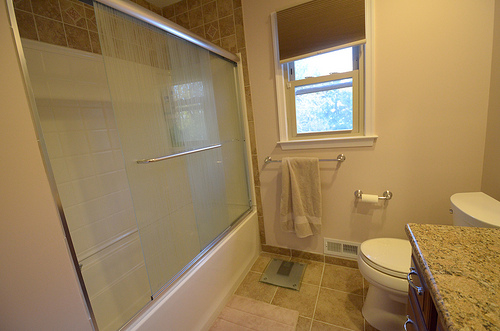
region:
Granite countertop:
[401, 204, 499, 321]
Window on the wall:
[248, 5, 398, 177]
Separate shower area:
[14, 4, 325, 314]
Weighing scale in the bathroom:
[261, 249, 321, 319]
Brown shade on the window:
[271, 1, 417, 101]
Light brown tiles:
[246, 283, 356, 328]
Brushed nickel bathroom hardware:
[99, 0, 433, 238]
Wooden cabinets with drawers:
[398, 242, 429, 329]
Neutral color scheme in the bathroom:
[4, 1, 493, 313]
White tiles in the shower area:
[51, 87, 228, 268]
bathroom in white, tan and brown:
[10, 13, 490, 318]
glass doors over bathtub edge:
[10, 6, 271, 321]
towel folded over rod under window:
[260, 146, 336, 242]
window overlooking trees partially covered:
[260, 1, 380, 151]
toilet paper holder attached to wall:
[342, 180, 392, 215]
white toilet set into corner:
[350, 147, 495, 317]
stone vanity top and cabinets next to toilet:
[400, 205, 492, 325]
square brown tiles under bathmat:
[230, 287, 362, 322]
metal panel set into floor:
[251, 245, 311, 290]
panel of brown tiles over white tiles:
[27, 0, 104, 133]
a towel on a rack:
[270, 153, 331, 237]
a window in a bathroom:
[263, 0, 384, 154]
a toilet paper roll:
[355, 189, 385, 206]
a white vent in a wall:
[320, 230, 371, 263]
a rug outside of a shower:
[212, 287, 305, 329]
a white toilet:
[348, 177, 498, 328]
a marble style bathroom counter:
[402, 215, 498, 329]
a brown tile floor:
[305, 278, 350, 328]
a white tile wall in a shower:
[40, 80, 110, 152]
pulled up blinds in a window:
[269, 0, 371, 65]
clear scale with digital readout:
[258, 255, 307, 289]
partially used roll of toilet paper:
[360, 192, 378, 202]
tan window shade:
[275, 3, 366, 55]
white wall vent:
[321, 234, 361, 258]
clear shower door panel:
[93, 2, 258, 296]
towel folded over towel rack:
[276, 156, 321, 239]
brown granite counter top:
[405, 220, 498, 330]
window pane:
[296, 78, 352, 130]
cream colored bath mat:
[211, 293, 298, 327]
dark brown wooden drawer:
[406, 247, 436, 324]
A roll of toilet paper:
[352, 184, 388, 212]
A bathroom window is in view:
[278, 10, 363, 139]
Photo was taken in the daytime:
[271, 8, 371, 142]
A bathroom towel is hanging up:
[273, 151, 330, 246]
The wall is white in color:
[384, 10, 480, 185]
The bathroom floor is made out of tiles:
[258, 259, 363, 329]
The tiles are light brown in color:
[260, 256, 358, 329]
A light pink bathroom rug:
[219, 290, 310, 329]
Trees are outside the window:
[296, 85, 353, 132]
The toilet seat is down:
[341, 178, 497, 328]